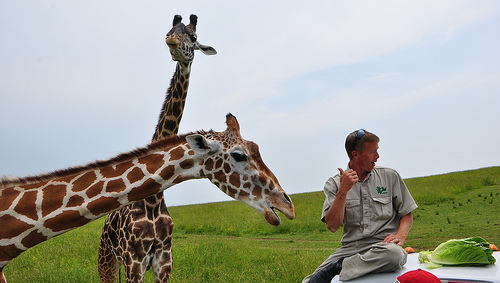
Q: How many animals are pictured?
A: 2.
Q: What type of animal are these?
A: Giraffes.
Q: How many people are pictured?
A: 1.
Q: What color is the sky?
A: Blue.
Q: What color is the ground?
A: Green.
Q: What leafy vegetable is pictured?
A: Lettuce.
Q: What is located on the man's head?
A: Sunglasses.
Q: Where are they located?
A: On safari.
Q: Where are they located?
A: On a field.